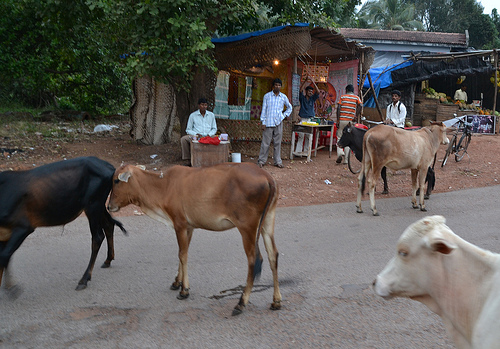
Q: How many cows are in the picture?
A: 5.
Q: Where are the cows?
A: In the road.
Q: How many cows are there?
A: 5.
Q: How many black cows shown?
A: 2.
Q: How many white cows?
A: 1.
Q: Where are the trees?
A: Behind the building.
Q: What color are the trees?
A: Green.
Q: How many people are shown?
A: 6.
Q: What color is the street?
A: Grey.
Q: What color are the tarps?
A: Blue.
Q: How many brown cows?
A: 2.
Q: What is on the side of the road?
A: Dirt.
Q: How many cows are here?
A: 5.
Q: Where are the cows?
A: In the road.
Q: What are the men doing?
A: Watching the cows.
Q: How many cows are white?
A: 1.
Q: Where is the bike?
A: Parked on dirt.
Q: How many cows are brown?
A: 2.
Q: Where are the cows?
A: In the road.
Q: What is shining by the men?
A: A light bulb.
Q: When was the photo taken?
A: Daytime.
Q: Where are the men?
A: Near the building.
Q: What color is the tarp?
A: Blue.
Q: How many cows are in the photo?
A: Five.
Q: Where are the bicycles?
A: On the side of the road.